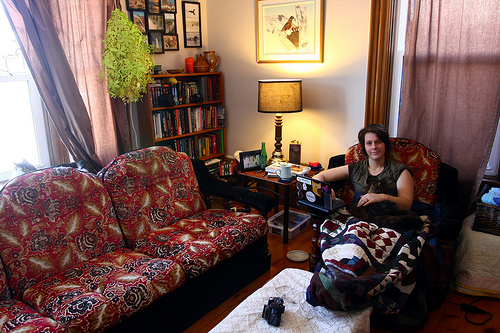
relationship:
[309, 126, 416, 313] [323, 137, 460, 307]
lady sitting in a chair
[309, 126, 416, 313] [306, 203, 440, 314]
lady with a blanket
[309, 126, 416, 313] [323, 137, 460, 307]
lady in a chair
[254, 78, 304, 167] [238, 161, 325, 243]
standing lamp on end of table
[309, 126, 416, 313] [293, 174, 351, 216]
lady with a laptop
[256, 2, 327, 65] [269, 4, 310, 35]
framed picture of birds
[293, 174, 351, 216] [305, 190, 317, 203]
laptop with sticker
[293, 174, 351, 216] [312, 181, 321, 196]
laptop with sticker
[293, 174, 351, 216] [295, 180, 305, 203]
laptop with sticker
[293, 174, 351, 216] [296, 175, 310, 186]
laptop with sticker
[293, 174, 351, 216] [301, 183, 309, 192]
laptop with sticker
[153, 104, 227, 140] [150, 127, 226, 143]
books on shelf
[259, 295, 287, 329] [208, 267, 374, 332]
camera on top of a stool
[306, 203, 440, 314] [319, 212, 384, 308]
quilt over legs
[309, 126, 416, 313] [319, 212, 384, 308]
lady has legs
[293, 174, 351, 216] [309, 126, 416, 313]
laptop open in front of lady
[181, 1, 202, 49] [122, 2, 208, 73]
picture hanging on wall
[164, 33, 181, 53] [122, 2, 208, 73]
picture hanging on wall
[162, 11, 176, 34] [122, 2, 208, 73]
picture hanging on wall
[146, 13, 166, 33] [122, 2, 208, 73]
picture hanging on wall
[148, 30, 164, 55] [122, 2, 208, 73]
picture hanging on wall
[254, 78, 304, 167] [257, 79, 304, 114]
table lamp with shade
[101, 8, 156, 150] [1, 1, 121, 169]
tree by window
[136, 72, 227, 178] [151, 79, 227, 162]
book shelf with lots of books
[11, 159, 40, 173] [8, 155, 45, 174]
head of a cat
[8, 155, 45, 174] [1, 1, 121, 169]
cat by window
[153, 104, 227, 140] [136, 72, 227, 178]
books in bookshelf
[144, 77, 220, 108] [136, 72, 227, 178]
books in bookshelf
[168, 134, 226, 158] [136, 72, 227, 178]
books in bookshelf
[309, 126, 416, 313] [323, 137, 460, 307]
lady sitting on chair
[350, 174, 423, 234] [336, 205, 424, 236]
cat on lap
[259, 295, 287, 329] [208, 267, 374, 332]
camera on top of table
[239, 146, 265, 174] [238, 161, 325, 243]
picture frame on side of table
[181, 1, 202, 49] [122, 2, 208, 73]
painting hanging on wall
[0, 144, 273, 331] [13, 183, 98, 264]
sofa with a crazy pattern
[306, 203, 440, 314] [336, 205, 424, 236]
quilt on top of lap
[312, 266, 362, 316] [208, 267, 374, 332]
feet propped up on an ottoman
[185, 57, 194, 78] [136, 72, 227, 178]
candle on top of book shelf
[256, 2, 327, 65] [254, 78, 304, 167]
wall art above lamp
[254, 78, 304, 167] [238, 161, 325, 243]
table lamp on top of table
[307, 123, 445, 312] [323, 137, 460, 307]
lady sitting on chair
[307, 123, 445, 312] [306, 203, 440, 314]
lady covering with multi color throw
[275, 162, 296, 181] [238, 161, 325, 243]
cup on top of table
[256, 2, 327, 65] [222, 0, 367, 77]
picture frame hanging on wall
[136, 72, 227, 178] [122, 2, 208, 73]
book shelf against wall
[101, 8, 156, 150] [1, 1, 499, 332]
potted plant in living room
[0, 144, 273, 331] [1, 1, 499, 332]
couch in living room